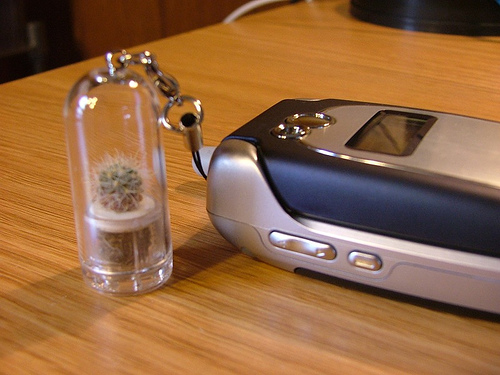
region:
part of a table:
[220, 298, 255, 359]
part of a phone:
[355, 245, 396, 327]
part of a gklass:
[134, 225, 166, 252]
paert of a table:
[232, 286, 259, 331]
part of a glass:
[136, 228, 168, 264]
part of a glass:
[129, 244, 189, 321]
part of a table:
[229, 305, 256, 340]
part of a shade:
[190, 230, 209, 261]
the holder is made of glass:
[26, 38, 189, 288]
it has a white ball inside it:
[48, 100, 200, 310]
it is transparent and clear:
[55, 70, 182, 316]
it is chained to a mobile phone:
[15, 35, 223, 260]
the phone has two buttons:
[208, 83, 494, 356]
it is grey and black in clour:
[187, 85, 497, 340]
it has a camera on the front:
[235, 75, 331, 147]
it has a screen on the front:
[337, 95, 433, 187]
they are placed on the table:
[57, 42, 493, 343]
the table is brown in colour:
[198, 33, 385, 94]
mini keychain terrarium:
[66, 48, 176, 294]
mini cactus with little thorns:
[84, 154, 153, 219]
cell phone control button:
[266, 228, 335, 262]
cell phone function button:
[345, 246, 382, 272]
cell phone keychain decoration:
[59, 43, 204, 298]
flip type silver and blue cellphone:
[213, 93, 498, 323]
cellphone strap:
[175, 108, 205, 174]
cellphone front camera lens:
[273, 107, 336, 137]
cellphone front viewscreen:
[348, 108, 438, 165]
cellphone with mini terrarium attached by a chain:
[57, 39, 497, 320]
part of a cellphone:
[323, 146, 356, 174]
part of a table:
[248, 277, 294, 364]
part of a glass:
[122, 219, 144, 242]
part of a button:
[351, 234, 386, 301]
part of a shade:
[224, 251, 256, 293]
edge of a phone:
[402, 229, 449, 296]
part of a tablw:
[219, 320, 246, 362]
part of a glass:
[110, 192, 152, 245]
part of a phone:
[339, 238, 388, 306]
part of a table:
[285, 15, 310, 46]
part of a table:
[215, 274, 261, 345]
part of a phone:
[379, 213, 430, 288]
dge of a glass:
[121, 257, 183, 325]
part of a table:
[228, 324, 258, 369]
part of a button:
[301, 227, 353, 267]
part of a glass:
[111, 250, 166, 325]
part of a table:
[216, 295, 246, 329]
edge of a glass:
[114, 265, 174, 314]